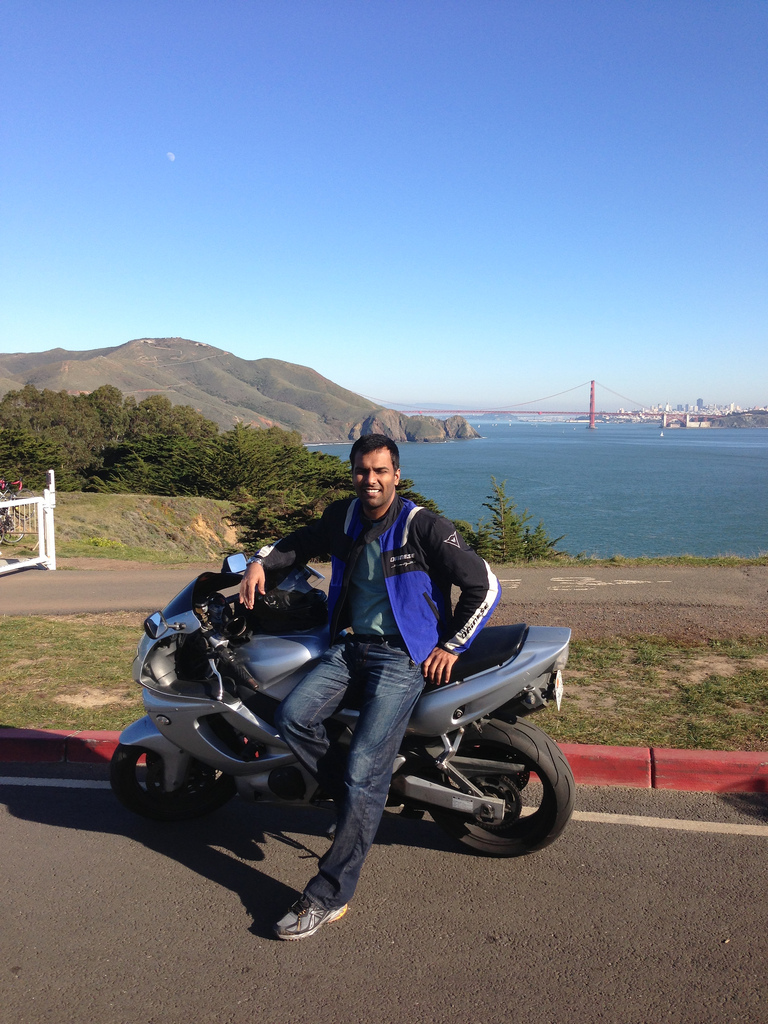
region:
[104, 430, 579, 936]
a man is leaning back on a motorcycle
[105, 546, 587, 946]
the bike is silver and black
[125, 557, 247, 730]
the bike has a windshield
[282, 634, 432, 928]
the man is wearing blue jeans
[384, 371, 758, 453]
the San Francisco Bridge is in the background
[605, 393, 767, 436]
the city of San Francisco is on the horizon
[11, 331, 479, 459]
hills are in the background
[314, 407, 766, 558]
San Francisco Bay is blue with a light chop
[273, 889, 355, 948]
the man is wearing sneakers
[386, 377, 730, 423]
Golden Gate Bridge spanning Golden Gate strait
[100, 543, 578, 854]
silver and black crotch rocket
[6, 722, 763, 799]
roadside curb painted red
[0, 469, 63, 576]
a white gate to a gravel road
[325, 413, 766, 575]
San Francisco Bay is blue and calm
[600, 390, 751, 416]
skyline of San Francisco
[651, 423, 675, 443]
a boat on the water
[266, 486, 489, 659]
man's jacket is blue black and white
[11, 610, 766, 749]
patchy grass along the road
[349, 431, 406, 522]
man squints into the sunlight and smiles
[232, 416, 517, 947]
Man posing for a picture.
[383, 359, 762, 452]
Red bridge in the background.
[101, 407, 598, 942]
Man sitting on the motorcycle.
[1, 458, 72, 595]
White fence in the background.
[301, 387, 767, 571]
Large body of water in the background.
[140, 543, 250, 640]
Rearview mirrors on the bike.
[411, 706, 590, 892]
the wheel is black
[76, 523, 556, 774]
the bike is silver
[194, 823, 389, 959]
the man is wearing sneakers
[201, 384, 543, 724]
the man is wearing a jacket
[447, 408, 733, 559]
the water is bluish green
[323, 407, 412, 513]
the man is smiling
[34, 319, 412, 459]
mountain in the background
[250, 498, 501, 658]
a blue, black, and white jacket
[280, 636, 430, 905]
a pair of blue jeans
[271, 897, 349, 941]
a gray colored shoe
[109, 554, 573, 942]
a silver colored motorcycle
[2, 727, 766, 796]
a red colored curb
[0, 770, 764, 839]
a white line on the gray pavement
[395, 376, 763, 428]
a red colored bridge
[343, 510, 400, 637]
a blue colored shirt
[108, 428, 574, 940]
a dark haired man leaning on a silver motorcycle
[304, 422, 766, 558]
a blue body of water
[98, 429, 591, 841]
man leaning on gray bike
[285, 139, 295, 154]
white clouds in blue sky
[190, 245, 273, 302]
white clouds in blue sky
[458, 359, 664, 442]
bridge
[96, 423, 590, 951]
A man posing on a motorcycle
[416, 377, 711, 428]
The Golden Gate bridge in the distance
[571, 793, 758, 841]
A white line on a road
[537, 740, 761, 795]
A red curb on the side of a road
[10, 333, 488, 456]
A mountain range next to an ocean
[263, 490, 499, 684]
A blue and white racing jacket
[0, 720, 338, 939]
The shadow of a man on pavement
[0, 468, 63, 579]
A white metal gate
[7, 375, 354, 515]
A group of trees next to the ocean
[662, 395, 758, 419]
A group of buildings next to a bridge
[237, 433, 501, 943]
a man with dark hair and wearing blue jeans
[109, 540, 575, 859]
a silver and black motorcycle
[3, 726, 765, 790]
a painted red curb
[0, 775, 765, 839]
a white line on the side of the road